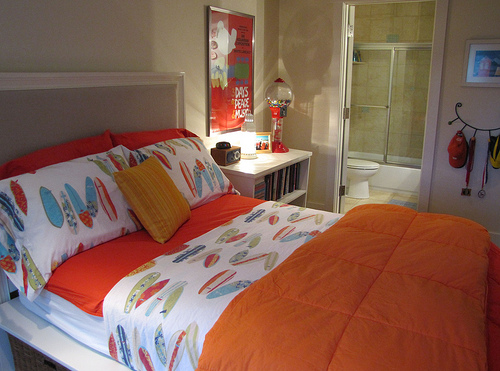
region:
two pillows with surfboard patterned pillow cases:
[0, 137, 240, 302]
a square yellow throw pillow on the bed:
[113, 155, 195, 244]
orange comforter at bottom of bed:
[198, 202, 498, 369]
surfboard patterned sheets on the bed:
[102, 200, 343, 368]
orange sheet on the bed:
[42, 192, 267, 317]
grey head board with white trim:
[0, 69, 188, 162]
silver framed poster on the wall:
[204, 5, 257, 135]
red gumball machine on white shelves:
[263, 75, 294, 153]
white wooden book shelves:
[216, 143, 312, 207]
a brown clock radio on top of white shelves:
[211, 140, 241, 165]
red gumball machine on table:
[267, 80, 297, 150]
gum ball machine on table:
[269, 80, 291, 148]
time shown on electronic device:
[209, 140, 247, 157]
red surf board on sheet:
[200, 259, 239, 302]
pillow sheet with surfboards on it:
[16, 172, 123, 262]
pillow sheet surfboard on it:
[162, 140, 237, 199]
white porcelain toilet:
[338, 139, 379, 201]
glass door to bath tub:
[353, 45, 431, 168]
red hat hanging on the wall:
[447, 117, 469, 173]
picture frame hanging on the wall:
[466, 43, 498, 93]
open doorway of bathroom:
[326, 3, 438, 209]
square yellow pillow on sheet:
[120, 157, 190, 241]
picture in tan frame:
[456, 36, 498, 88]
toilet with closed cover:
[343, 156, 375, 201]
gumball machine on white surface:
[265, 75, 300, 160]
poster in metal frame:
[203, 4, 258, 139]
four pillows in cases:
[5, 126, 217, 269]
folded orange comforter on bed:
[198, 203, 493, 367]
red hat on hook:
[445, 127, 470, 170]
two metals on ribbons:
[457, 133, 494, 199]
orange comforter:
[195, 201, 495, 366]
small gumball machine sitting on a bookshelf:
[263, 75, 293, 155]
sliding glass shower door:
[345, 40, 430, 165]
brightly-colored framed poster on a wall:
[205, 0, 255, 135]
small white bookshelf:
[215, 140, 310, 210]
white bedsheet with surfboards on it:
[100, 195, 345, 365]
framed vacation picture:
[250, 130, 270, 150]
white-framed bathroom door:
[332, 0, 448, 215]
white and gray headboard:
[0, 73, 185, 160]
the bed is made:
[36, 131, 380, 358]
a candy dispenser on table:
[258, 68, 293, 165]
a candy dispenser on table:
[250, 68, 325, 170]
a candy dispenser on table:
[241, 67, 347, 223]